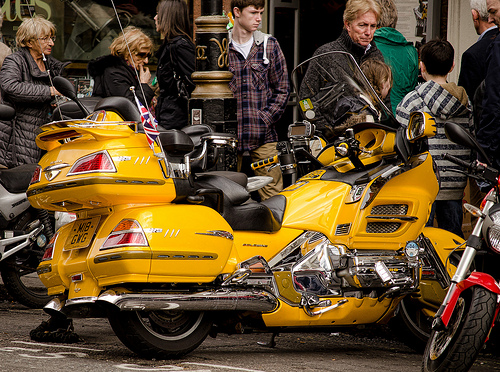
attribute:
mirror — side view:
[408, 109, 433, 144]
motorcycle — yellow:
[27, 106, 476, 356]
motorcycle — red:
[407, 120, 484, 351]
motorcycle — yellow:
[17, 83, 489, 363]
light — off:
[61, 144, 121, 180]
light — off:
[24, 163, 45, 184]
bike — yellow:
[23, 49, 480, 349]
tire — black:
[107, 305, 218, 356]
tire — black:
[420, 284, 493, 370]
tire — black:
[390, 298, 436, 351]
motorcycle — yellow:
[56, 109, 436, 341]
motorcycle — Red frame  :
[429, 191, 481, 369]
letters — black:
[68, 217, 93, 244]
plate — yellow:
[59, 213, 101, 253]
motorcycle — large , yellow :
[47, 123, 436, 316]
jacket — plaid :
[218, 39, 287, 131]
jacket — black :
[4, 46, 41, 172]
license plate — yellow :
[61, 219, 107, 251]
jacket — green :
[380, 36, 418, 92]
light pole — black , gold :
[197, 8, 234, 149]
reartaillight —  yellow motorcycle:
[37, 150, 160, 277]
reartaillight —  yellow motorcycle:
[74, 145, 158, 264]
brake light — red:
[70, 151, 116, 179]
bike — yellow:
[21, 82, 471, 352]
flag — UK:
[132, 96, 168, 153]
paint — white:
[11, 340, 246, 369]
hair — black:
[414, 39, 449, 73]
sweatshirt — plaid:
[224, 30, 275, 137]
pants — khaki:
[242, 134, 296, 194]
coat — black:
[155, 26, 202, 118]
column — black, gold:
[193, 8, 245, 178]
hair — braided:
[355, 54, 390, 97]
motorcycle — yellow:
[25, 36, 495, 366]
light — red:
[72, 143, 120, 173]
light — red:
[97, 214, 155, 250]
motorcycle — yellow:
[33, 106, 454, 326]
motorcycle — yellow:
[37, 96, 447, 341]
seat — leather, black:
[204, 168, 277, 230]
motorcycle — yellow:
[17, 103, 438, 332]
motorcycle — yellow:
[23, 50, 469, 358]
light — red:
[69, 148, 104, 175]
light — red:
[115, 227, 136, 245]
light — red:
[40, 232, 52, 259]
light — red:
[28, 163, 38, 185]